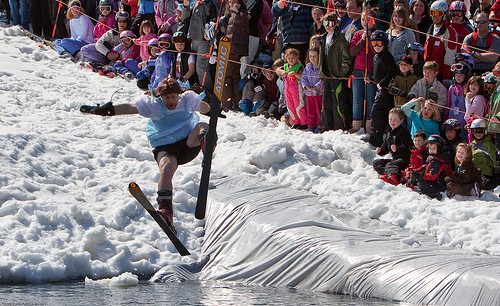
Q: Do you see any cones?
A: No, there are no cones.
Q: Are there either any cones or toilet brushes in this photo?
A: No, there are no cones or toilet brushes.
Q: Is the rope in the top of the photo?
A: Yes, the rope is in the top of the image.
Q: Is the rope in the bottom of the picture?
A: No, the rope is in the top of the image.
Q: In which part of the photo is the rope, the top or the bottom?
A: The rope is in the top of the image.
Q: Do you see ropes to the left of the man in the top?
A: Yes, there is a rope to the left of the man.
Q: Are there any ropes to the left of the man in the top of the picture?
A: Yes, there is a rope to the left of the man.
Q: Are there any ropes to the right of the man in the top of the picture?
A: No, the rope is to the left of the man.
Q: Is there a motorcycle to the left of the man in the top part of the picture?
A: No, there is a rope to the left of the man.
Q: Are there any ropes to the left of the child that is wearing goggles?
A: Yes, there is a rope to the left of the kid.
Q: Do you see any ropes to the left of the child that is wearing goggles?
A: Yes, there is a rope to the left of the kid.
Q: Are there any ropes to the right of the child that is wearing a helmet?
A: No, the rope is to the left of the kid.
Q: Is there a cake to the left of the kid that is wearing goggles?
A: No, there is a rope to the left of the child.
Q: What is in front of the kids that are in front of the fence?
A: The rope is in front of the children.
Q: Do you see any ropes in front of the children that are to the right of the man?
A: Yes, there is a rope in front of the kids.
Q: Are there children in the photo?
A: Yes, there is a child.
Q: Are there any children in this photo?
A: Yes, there is a child.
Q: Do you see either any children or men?
A: Yes, there is a child.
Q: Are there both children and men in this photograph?
A: Yes, there are both a child and a man.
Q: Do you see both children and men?
A: Yes, there are both a child and a man.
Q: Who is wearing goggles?
A: The kid is wearing goggles.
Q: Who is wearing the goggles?
A: The kid is wearing goggles.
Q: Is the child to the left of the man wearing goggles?
A: Yes, the child is wearing goggles.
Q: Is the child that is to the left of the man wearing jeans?
A: No, the kid is wearing goggles.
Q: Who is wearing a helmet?
A: The kid is wearing a helmet.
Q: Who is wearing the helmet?
A: The kid is wearing a helmet.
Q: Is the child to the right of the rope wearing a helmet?
A: Yes, the kid is wearing a helmet.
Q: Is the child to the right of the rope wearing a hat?
A: No, the child is wearing a helmet.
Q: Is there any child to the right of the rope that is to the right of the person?
A: Yes, there is a child to the right of the rope.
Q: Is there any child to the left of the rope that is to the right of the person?
A: No, the child is to the right of the rope.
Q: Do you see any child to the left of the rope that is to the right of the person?
A: No, the child is to the right of the rope.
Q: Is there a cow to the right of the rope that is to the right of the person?
A: No, there is a child to the right of the rope.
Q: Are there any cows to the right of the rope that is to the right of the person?
A: No, there is a child to the right of the rope.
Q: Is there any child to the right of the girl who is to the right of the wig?
A: Yes, there is a child to the right of the girl.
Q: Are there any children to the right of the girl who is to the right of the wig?
A: Yes, there is a child to the right of the girl.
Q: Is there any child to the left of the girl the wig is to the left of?
A: No, the child is to the right of the girl.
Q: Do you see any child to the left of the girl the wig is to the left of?
A: No, the child is to the right of the girl.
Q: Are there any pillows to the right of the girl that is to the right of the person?
A: No, there is a child to the right of the girl.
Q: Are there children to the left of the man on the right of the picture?
A: Yes, there is a child to the left of the man.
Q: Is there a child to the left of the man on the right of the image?
A: Yes, there is a child to the left of the man.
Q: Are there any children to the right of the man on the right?
A: No, the child is to the left of the man.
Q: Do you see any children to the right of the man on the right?
A: No, the child is to the left of the man.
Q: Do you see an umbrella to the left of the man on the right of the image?
A: No, there is a child to the left of the man.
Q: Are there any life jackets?
A: No, there are no life jackets.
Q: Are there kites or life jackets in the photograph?
A: No, there are no life jackets or kites.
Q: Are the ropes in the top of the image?
A: Yes, the ropes are in the top of the image.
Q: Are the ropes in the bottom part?
A: No, the ropes are in the top of the image.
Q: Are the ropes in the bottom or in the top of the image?
A: The ropes are in the top of the image.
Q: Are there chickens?
A: No, there are no chickens.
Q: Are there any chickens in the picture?
A: No, there are no chickens.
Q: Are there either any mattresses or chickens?
A: No, there are no chickens or mattresses.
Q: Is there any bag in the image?
A: No, there are no bags.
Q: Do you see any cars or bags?
A: No, there are no bags or cars.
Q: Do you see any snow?
A: Yes, there is snow.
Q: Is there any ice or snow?
A: Yes, there is snow.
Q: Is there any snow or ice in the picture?
A: Yes, there is snow.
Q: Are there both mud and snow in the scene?
A: No, there is snow but no mud.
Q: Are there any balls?
A: No, there are no balls.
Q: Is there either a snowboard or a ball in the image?
A: No, there are no balls or snowboards.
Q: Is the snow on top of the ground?
A: Yes, the snow is on top of the ground.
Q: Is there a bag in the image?
A: No, there are no bags.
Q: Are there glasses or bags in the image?
A: No, there are no bags or glasses.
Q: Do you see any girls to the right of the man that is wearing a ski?
A: Yes, there is a girl to the right of the man.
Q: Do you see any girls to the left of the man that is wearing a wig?
A: No, the girl is to the right of the man.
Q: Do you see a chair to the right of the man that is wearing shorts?
A: No, there is a girl to the right of the man.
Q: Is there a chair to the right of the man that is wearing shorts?
A: No, there is a girl to the right of the man.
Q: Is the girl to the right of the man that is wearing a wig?
A: Yes, the girl is to the right of the man.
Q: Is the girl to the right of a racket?
A: No, the girl is to the right of the man.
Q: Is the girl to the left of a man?
A: No, the girl is to the right of a man.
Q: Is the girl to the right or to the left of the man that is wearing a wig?
A: The girl is to the right of the man.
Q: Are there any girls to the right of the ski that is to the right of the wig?
A: Yes, there is a girl to the right of the ski.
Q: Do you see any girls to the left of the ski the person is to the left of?
A: No, the girl is to the right of the ski.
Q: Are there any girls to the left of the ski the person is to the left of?
A: No, the girl is to the right of the ski.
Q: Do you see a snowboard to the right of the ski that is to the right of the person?
A: No, there is a girl to the right of the ski.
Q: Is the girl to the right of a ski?
A: Yes, the girl is to the right of a ski.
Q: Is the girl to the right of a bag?
A: No, the girl is to the right of a ski.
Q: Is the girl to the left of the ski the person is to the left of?
A: No, the girl is to the right of the ski.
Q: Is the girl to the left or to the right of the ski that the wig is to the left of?
A: The girl is to the right of the ski.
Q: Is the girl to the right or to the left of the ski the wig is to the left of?
A: The girl is to the right of the ski.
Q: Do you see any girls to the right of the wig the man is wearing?
A: Yes, there is a girl to the right of the wig.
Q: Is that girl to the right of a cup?
A: No, the girl is to the right of the wig.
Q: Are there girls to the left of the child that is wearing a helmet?
A: Yes, there is a girl to the left of the child.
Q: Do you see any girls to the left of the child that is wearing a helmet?
A: Yes, there is a girl to the left of the child.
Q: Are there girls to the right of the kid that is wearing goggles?
A: No, the girl is to the left of the kid.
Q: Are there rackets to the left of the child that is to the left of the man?
A: No, there is a girl to the left of the child.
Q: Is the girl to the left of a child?
A: Yes, the girl is to the left of a child.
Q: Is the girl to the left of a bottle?
A: No, the girl is to the left of a child.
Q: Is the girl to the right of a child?
A: No, the girl is to the left of a child.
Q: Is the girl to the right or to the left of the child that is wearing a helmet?
A: The girl is to the left of the child.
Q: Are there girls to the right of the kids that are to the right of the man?
A: Yes, there is a girl to the right of the children.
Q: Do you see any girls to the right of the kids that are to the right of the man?
A: Yes, there is a girl to the right of the children.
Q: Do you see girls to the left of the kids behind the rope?
A: No, the girl is to the right of the kids.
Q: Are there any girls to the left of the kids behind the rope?
A: No, the girl is to the right of the kids.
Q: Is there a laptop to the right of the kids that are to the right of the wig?
A: No, there is a girl to the right of the kids.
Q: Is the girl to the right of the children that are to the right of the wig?
A: Yes, the girl is to the right of the children.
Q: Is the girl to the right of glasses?
A: No, the girl is to the right of the children.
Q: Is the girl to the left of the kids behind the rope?
A: No, the girl is to the right of the kids.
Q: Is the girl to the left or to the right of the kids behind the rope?
A: The girl is to the right of the kids.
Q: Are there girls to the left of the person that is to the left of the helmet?
A: Yes, there is a girl to the left of the person.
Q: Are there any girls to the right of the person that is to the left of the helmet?
A: No, the girl is to the left of the person.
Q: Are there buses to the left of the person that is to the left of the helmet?
A: No, there is a girl to the left of the person.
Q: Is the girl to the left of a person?
A: Yes, the girl is to the left of a person.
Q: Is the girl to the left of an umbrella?
A: No, the girl is to the left of a person.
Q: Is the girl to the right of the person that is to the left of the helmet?
A: No, the girl is to the left of the person.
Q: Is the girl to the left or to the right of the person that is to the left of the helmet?
A: The girl is to the left of the person.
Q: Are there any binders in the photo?
A: No, there are no binders.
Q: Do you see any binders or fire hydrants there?
A: No, there are no binders or fire hydrants.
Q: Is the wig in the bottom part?
A: No, the wig is in the top of the image.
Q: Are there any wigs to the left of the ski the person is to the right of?
A: Yes, there is a wig to the left of the ski.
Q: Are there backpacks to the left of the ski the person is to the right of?
A: No, there is a wig to the left of the ski.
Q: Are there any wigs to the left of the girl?
A: Yes, there is a wig to the left of the girl.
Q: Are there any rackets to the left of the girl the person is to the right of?
A: No, there is a wig to the left of the girl.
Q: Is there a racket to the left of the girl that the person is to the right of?
A: No, there is a wig to the left of the girl.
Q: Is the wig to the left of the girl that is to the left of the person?
A: Yes, the wig is to the left of the girl.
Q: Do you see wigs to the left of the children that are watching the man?
A: Yes, there is a wig to the left of the kids.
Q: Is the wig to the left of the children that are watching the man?
A: Yes, the wig is to the left of the kids.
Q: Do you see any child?
A: Yes, there are children.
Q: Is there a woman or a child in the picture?
A: Yes, there are children.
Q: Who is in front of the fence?
A: The kids are in front of the fence.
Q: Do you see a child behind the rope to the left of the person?
A: Yes, there are children behind the rope.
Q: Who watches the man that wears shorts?
A: The children watch the man.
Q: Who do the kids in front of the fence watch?
A: The children watch the man.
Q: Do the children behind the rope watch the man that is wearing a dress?
A: Yes, the children watch the man.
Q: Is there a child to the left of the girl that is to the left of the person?
A: Yes, there are children to the left of the girl.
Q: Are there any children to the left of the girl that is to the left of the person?
A: Yes, there are children to the left of the girl.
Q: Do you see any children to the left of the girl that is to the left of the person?
A: Yes, there are children to the left of the girl.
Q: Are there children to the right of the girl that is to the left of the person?
A: No, the children are to the left of the girl.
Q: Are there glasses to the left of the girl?
A: No, there are children to the left of the girl.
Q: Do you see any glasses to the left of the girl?
A: No, there are children to the left of the girl.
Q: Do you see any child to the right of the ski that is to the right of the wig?
A: Yes, there are children to the right of the ski.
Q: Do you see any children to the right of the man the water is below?
A: Yes, there are children to the right of the man.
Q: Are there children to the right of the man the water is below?
A: Yes, there are children to the right of the man.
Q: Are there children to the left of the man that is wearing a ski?
A: No, the children are to the right of the man.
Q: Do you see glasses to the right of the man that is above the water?
A: No, there are children to the right of the man.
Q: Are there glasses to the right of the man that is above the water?
A: No, there are children to the right of the man.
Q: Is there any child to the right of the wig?
A: Yes, there are children to the right of the wig.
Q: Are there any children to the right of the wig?
A: Yes, there are children to the right of the wig.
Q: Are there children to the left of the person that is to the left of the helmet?
A: Yes, there are children to the left of the person.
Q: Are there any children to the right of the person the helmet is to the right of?
A: No, the children are to the left of the person.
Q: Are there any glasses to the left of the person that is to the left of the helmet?
A: No, there are children to the left of the person.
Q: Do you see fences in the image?
A: Yes, there is a fence.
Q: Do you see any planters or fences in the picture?
A: Yes, there is a fence.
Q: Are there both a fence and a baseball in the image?
A: No, there is a fence but no baseballs.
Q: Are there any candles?
A: No, there are no candles.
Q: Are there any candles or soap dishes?
A: No, there are no candles or soap dishes.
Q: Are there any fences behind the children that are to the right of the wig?
A: Yes, there is a fence behind the children.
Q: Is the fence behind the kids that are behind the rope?
A: Yes, the fence is behind the kids.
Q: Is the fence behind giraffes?
A: No, the fence is behind the kids.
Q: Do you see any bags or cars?
A: No, there are no cars or bags.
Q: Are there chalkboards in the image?
A: No, there are no chalkboards.